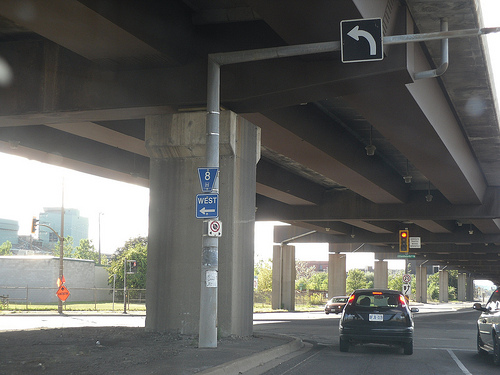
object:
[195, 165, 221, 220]
black jacket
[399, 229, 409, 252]
signal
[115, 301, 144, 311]
green grass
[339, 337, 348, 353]
wheel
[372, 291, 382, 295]
brake light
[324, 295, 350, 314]
car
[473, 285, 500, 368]
cars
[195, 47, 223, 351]
pole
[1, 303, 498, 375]
street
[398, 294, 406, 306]
brake light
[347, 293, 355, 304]
brake light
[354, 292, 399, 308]
window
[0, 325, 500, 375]
island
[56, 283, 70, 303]
sign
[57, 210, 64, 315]
pole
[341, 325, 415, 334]
bumper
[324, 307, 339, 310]
bumper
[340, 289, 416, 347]
back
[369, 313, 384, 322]
license tag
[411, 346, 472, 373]
marker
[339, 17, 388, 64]
sign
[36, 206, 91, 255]
buildings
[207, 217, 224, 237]
sign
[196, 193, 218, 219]
sign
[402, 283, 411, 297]
sign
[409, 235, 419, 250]
sign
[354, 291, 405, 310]
back window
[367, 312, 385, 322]
plate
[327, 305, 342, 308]
headlights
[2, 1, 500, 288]
bridge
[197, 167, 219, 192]
sign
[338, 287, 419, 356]
car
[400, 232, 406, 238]
red light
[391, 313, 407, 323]
brake light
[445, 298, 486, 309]
turn